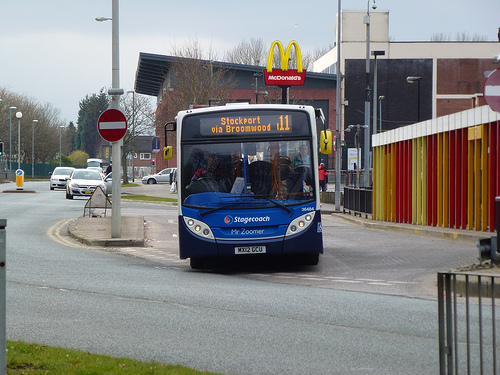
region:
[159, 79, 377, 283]
Bus provides public transportation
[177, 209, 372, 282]
Stagecoach is the bus' company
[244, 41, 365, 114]
McDonald's serves food to the public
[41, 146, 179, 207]
Four vehicles behind the bus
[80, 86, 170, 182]
Street sign controls traffic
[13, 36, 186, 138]
Overcast weather is seen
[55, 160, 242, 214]
All sedans seen are silver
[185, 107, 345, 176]
This gives the transportation information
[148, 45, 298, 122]
This tree is dead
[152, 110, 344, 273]
The bus is blue, gray, and silver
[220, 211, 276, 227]
The name of the bus manufacturer.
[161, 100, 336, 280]
A large bus transporting people.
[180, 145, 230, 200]
The man driving the bus.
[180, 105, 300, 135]
The name of the bus' destination.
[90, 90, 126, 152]
A white minus sign circumscribed by a red circle.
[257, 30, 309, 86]
A large McDonald's sign.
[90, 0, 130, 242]
A streetlight.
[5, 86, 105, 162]
A group of trees in the background.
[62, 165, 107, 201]
A white car.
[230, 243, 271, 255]
The bus' license plate.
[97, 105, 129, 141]
Red and white no entry sign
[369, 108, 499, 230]
Red and yellow fence slats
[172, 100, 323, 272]
Blue and black stagecoach bus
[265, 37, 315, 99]
Yellow and red McDonalds sign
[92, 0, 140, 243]
Grey street light post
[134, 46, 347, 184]
Brick building with grey roof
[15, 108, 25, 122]
Round street light globe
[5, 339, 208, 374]
Grass growing along the curb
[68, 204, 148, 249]
Concrete median in the street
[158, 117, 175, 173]
Black post with yellow sign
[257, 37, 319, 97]
A MCDONALD'S SIGN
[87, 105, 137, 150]
RED AND WHITE STREET SIGN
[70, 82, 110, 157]
TREES IN THE DISTANCE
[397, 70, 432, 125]
A TALL STREET LIGHT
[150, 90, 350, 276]
THE NUMBER 11 BUS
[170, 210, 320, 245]
A SET OF BUS HEADLIGHTS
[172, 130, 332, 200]
A BUS WINDSHIELD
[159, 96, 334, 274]
A PASSENGER BUS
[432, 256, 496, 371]
A METAL FENCE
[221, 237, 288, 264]
LICENSE PLATE ON A BUS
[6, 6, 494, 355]
Public bus in a town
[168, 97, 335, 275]
blue bus with gold and white lettering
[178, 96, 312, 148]
Bus #11 Stockport via Broonwood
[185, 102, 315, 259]
Stagecoach brand bus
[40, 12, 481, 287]
McDonalds sign in the background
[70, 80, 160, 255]
Do not enter sign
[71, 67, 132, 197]
Do not enter sign hanging on a steel pole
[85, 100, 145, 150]
red and white do not enter sign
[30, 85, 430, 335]
parked cars in the background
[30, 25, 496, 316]
large building in the background